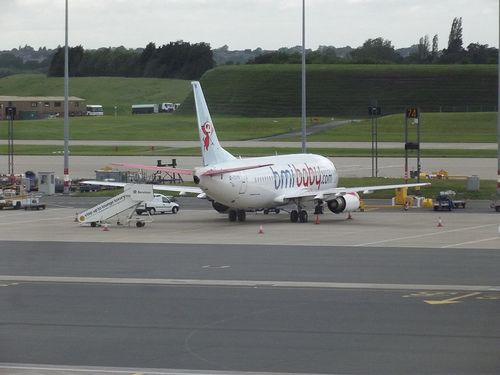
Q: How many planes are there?
A: One.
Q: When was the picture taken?
A: Daytime.